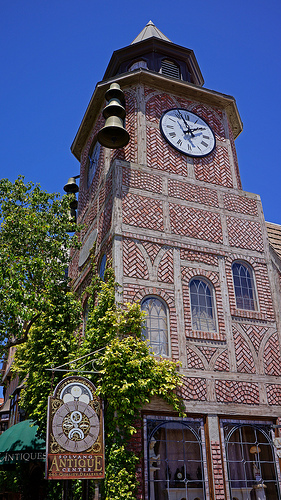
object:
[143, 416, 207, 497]
glass windows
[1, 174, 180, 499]
brooms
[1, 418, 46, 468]
awning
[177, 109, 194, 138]
hand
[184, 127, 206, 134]
hand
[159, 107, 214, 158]
clock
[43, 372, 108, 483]
sign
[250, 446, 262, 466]
lamp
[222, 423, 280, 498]
window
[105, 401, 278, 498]
ground floor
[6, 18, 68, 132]
sky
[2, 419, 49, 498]
entryway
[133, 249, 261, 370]
windows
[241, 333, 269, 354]
design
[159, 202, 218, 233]
design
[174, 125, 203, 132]
hand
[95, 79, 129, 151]
bells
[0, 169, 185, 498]
lush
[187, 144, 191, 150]
six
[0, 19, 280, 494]
building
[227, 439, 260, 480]
panes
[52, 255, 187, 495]
ivy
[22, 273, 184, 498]
tree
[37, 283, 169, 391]
leaves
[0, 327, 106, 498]
antique store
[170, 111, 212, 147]
face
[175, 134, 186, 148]
roman numerals